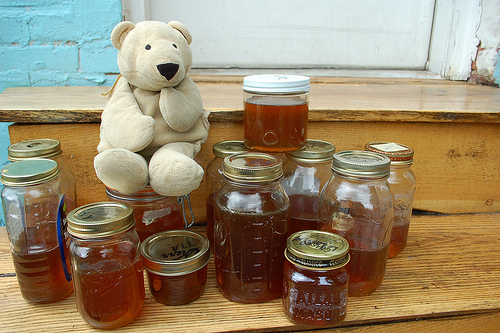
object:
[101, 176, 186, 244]
jar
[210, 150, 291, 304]
jar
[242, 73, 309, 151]
jar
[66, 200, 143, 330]
jar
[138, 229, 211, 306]
jar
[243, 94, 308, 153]
honey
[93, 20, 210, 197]
bear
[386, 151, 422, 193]
wall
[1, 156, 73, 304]
jar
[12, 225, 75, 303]
honey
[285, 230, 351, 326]
pint jar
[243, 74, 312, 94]
lid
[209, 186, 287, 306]
honey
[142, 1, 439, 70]
door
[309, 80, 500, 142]
steps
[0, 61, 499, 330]
wooden steps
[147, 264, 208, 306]
honey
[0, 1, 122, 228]
brick wall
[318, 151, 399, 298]
jar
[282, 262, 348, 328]
liquid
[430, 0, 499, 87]
peeling/cracked/old paint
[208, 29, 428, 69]
window pane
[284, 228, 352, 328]
jar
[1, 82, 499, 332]
counter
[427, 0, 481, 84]
door frame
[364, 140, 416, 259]
jar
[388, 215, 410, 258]
liquid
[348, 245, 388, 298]
liquid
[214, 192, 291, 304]
liquid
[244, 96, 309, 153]
liquid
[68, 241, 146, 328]
liquid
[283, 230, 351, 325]
mason jar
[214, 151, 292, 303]
mason jar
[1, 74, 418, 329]
bottles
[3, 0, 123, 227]
paint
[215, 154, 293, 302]
jar